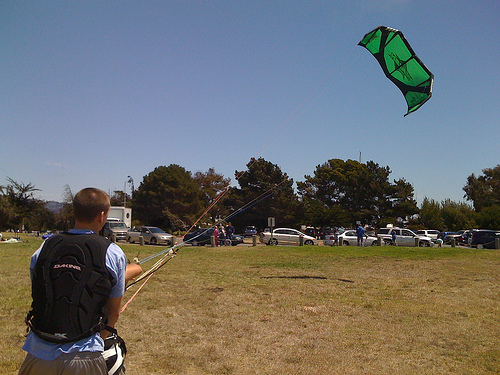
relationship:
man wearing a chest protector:
[19, 186, 127, 374] [25, 232, 118, 344]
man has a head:
[19, 186, 127, 374] [74, 188, 110, 233]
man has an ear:
[19, 186, 127, 374] [100, 211, 105, 220]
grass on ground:
[0, 232, 499, 374] [1, 233, 500, 374]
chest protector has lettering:
[25, 232, 118, 344] [53, 264, 82, 271]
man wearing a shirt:
[19, 186, 127, 374] [23, 230, 126, 361]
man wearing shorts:
[19, 186, 127, 374] [18, 353, 109, 375]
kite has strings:
[358, 24, 435, 117] [122, 44, 405, 315]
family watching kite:
[214, 223, 234, 244] [358, 24, 435, 117]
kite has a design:
[358, 24, 435, 117] [387, 53, 412, 80]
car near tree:
[324, 229, 379, 246] [296, 159, 419, 236]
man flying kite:
[19, 186, 127, 374] [358, 24, 435, 117]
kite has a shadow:
[358, 24, 435, 117] [262, 276, 352, 284]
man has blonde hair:
[19, 186, 127, 374] [74, 187, 111, 223]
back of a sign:
[266, 215, 276, 226] [268, 217, 276, 227]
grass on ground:
[0, 232, 499, 374] [232, 240, 447, 371]